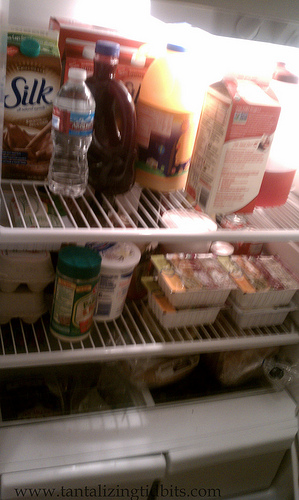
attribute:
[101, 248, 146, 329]
container — plastic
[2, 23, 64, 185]
carton — white, red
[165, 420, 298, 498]
carton — red, white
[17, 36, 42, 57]
cap — green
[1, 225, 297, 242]
bar — white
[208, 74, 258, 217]
carton — red, white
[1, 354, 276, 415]
shelf — glass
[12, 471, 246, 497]
website — black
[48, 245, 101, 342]
container — Parmesan cheese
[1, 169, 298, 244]
shelf — white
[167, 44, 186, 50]
cap — blue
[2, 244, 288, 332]
bar — white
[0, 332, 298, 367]
bar — white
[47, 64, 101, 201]
bottle — water 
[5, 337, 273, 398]
bar — white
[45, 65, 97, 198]
bottle — water, clear, plastic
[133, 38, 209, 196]
juice — orange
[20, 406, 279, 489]
drawers — white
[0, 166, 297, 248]
bar — white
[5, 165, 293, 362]
bar — white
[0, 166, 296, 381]
bar — white